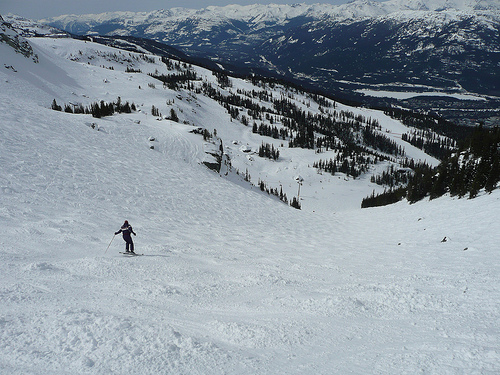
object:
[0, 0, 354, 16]
sky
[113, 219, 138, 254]
skier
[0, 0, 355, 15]
clouds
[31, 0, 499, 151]
hill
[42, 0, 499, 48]
hill side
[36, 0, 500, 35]
snow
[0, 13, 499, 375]
snow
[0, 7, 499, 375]
hillside